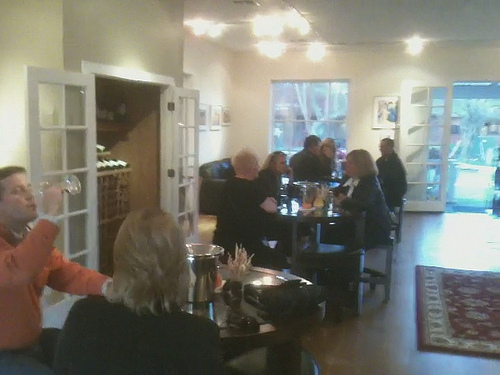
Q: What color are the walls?
A: White.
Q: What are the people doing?
A: Eating.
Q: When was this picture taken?
A: Daytime.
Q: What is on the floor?
A: A rug.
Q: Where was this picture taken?
A: A dining room.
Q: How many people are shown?
A: Eight.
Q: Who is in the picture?
A: Men and women.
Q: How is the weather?
A: Sunny.